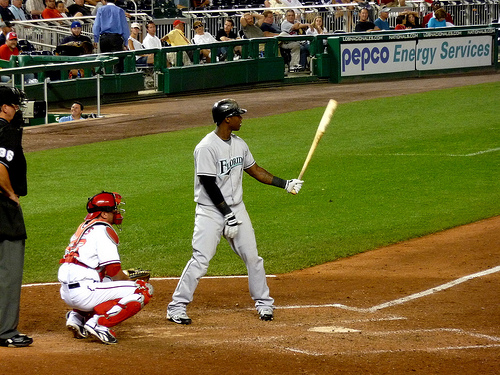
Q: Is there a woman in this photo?
A: No, there are no women.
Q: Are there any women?
A: No, there are no women.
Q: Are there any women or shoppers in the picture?
A: No, there are no women or shoppers.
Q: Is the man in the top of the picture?
A: Yes, the man is in the top of the image.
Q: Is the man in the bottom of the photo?
A: No, the man is in the top of the image.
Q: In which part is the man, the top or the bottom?
A: The man is in the top of the image.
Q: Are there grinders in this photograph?
A: No, there are no grinders.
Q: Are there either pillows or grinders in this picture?
A: No, there are no grinders or pillows.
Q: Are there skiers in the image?
A: No, there are no skiers.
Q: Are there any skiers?
A: No, there are no skiers.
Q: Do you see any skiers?
A: No, there are no skiers.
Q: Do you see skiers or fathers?
A: No, there are no skiers or fathers.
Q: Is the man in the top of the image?
A: Yes, the man is in the top of the image.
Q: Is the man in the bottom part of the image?
A: No, the man is in the top of the image.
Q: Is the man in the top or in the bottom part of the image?
A: The man is in the top of the image.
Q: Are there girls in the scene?
A: No, there are no girls.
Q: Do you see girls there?
A: No, there are no girls.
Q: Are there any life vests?
A: No, there are no life vests.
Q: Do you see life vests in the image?
A: No, there are no life vests.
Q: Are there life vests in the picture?
A: No, there are no life vests.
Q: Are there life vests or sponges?
A: No, there are no life vests or sponges.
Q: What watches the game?
A: The fan watches the game.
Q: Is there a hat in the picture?
A: Yes, there is a hat.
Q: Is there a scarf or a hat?
A: Yes, there is a hat.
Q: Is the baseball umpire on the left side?
A: Yes, the umpire is on the left of the image.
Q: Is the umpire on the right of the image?
A: No, the umpire is on the left of the image.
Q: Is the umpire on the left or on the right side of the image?
A: The umpire is on the left of the image.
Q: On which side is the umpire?
A: The umpire is on the left of the image.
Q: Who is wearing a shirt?
A: The umpire is wearing a shirt.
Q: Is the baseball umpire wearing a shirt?
A: Yes, the umpire is wearing a shirt.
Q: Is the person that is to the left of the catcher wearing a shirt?
A: Yes, the umpire is wearing a shirt.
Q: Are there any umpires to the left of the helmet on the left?
A: Yes, there is an umpire to the left of the helmet.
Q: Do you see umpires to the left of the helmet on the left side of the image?
A: Yes, there is an umpire to the left of the helmet.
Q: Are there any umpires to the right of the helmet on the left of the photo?
A: No, the umpire is to the left of the helmet.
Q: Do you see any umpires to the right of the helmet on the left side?
A: No, the umpire is to the left of the helmet.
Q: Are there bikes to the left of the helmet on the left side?
A: No, there is an umpire to the left of the helmet.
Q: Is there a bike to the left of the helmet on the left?
A: No, there is an umpire to the left of the helmet.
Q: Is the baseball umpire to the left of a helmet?
A: Yes, the umpire is to the left of a helmet.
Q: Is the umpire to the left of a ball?
A: No, the umpire is to the left of a helmet.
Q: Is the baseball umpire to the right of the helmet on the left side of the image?
A: No, the umpire is to the left of the helmet.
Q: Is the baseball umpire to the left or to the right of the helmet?
A: The umpire is to the left of the helmet.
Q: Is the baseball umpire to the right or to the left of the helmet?
A: The umpire is to the left of the helmet.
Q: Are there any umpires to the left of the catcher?
A: Yes, there is an umpire to the left of the catcher.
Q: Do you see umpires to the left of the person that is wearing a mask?
A: Yes, there is an umpire to the left of the catcher.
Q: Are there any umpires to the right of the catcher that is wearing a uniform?
A: No, the umpire is to the left of the catcher.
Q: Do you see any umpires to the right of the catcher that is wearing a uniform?
A: No, the umpire is to the left of the catcher.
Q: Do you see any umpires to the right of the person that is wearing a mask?
A: No, the umpire is to the left of the catcher.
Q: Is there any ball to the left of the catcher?
A: No, there is an umpire to the left of the catcher.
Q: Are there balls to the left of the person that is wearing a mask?
A: No, there is an umpire to the left of the catcher.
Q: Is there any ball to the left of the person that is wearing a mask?
A: No, there is an umpire to the left of the catcher.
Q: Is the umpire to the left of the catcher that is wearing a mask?
A: Yes, the umpire is to the left of the catcher.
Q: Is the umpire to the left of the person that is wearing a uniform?
A: Yes, the umpire is to the left of the catcher.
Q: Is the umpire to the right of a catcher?
A: No, the umpire is to the left of a catcher.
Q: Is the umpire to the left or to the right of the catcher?
A: The umpire is to the left of the catcher.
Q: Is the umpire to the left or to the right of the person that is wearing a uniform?
A: The umpire is to the left of the catcher.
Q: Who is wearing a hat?
A: The umpire is wearing a hat.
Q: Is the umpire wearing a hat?
A: Yes, the umpire is wearing a hat.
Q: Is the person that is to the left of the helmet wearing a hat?
A: Yes, the umpire is wearing a hat.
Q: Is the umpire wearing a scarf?
A: No, the umpire is wearing a hat.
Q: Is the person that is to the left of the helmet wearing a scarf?
A: No, the umpire is wearing a hat.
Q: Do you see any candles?
A: No, there are no candles.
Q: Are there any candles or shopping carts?
A: No, there are no candles or shopping carts.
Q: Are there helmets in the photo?
A: Yes, there is a helmet.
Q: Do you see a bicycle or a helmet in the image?
A: Yes, there is a helmet.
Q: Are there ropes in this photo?
A: No, there are no ropes.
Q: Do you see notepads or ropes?
A: No, there are no ropes or notepads.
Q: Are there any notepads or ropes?
A: No, there are no ropes or notepads.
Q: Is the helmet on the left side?
A: Yes, the helmet is on the left of the image.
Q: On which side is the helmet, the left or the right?
A: The helmet is on the left of the image.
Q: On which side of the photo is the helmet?
A: The helmet is on the left of the image.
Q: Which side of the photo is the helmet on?
A: The helmet is on the left of the image.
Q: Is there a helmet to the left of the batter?
A: Yes, there is a helmet to the left of the batter.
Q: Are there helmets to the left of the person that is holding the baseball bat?
A: Yes, there is a helmet to the left of the batter.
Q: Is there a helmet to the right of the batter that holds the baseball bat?
A: No, the helmet is to the left of the batter.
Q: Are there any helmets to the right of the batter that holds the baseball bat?
A: No, the helmet is to the left of the batter.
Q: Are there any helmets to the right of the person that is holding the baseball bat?
A: No, the helmet is to the left of the batter.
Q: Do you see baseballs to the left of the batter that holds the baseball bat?
A: No, there is a helmet to the left of the batter.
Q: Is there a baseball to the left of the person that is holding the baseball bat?
A: No, there is a helmet to the left of the batter.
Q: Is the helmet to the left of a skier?
A: No, the helmet is to the left of a batter.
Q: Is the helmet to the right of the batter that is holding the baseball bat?
A: No, the helmet is to the left of the batter.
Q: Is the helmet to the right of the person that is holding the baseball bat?
A: No, the helmet is to the left of the batter.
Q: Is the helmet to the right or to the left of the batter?
A: The helmet is to the left of the batter.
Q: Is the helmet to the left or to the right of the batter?
A: The helmet is to the left of the batter.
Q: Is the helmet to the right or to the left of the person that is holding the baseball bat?
A: The helmet is to the left of the batter.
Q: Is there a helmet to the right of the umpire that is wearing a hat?
A: Yes, there is a helmet to the right of the umpire.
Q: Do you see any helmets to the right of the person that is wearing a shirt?
A: Yes, there is a helmet to the right of the umpire.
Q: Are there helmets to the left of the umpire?
A: No, the helmet is to the right of the umpire.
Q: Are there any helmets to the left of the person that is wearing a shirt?
A: No, the helmet is to the right of the umpire.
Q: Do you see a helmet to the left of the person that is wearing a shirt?
A: No, the helmet is to the right of the umpire.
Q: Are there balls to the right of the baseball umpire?
A: No, there is a helmet to the right of the umpire.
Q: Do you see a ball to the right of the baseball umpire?
A: No, there is a helmet to the right of the umpire.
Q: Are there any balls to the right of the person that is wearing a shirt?
A: No, there is a helmet to the right of the umpire.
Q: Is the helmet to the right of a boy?
A: No, the helmet is to the right of the umpire.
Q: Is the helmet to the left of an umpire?
A: No, the helmet is to the right of an umpire.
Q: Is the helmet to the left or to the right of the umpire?
A: The helmet is to the right of the umpire.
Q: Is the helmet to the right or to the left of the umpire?
A: The helmet is to the right of the umpire.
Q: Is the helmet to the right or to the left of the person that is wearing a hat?
A: The helmet is to the right of the umpire.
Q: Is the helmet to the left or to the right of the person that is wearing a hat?
A: The helmet is to the right of the umpire.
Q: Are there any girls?
A: No, there are no girls.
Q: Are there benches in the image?
A: No, there are no benches.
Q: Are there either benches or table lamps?
A: No, there are no benches or table lamps.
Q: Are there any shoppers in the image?
A: No, there are no shoppers.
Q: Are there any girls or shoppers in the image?
A: No, there are no shoppers or girls.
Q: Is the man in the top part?
A: Yes, the man is in the top of the image.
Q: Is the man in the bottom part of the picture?
A: No, the man is in the top of the image.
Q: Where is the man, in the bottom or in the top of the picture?
A: The man is in the top of the image.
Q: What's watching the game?
A: The fan is watching the game.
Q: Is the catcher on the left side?
A: Yes, the catcher is on the left of the image.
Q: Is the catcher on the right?
A: No, the catcher is on the left of the image.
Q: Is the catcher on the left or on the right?
A: The catcher is on the left of the image.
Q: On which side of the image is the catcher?
A: The catcher is on the left of the image.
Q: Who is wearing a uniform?
A: The catcher is wearing a uniform.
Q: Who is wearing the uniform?
A: The catcher is wearing a uniform.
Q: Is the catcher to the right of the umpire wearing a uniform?
A: Yes, the catcher is wearing a uniform.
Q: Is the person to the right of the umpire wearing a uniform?
A: Yes, the catcher is wearing a uniform.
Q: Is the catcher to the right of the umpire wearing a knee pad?
A: No, the catcher is wearing a uniform.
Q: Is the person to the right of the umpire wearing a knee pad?
A: No, the catcher is wearing a uniform.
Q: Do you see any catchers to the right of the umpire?
A: Yes, there is a catcher to the right of the umpire.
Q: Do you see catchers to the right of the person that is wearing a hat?
A: Yes, there is a catcher to the right of the umpire.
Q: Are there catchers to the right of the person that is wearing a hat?
A: Yes, there is a catcher to the right of the umpire.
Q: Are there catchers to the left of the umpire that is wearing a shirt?
A: No, the catcher is to the right of the umpire.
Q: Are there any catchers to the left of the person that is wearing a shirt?
A: No, the catcher is to the right of the umpire.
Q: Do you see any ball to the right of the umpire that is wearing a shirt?
A: No, there is a catcher to the right of the umpire.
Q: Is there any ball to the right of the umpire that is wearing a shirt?
A: No, there is a catcher to the right of the umpire.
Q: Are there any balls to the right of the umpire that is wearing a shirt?
A: No, there is a catcher to the right of the umpire.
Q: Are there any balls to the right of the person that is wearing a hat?
A: No, there is a catcher to the right of the umpire.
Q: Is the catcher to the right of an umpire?
A: Yes, the catcher is to the right of an umpire.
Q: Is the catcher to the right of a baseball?
A: No, the catcher is to the right of an umpire.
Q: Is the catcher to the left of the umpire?
A: No, the catcher is to the right of the umpire.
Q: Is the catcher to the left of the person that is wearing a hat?
A: No, the catcher is to the right of the umpire.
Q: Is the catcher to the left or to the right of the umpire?
A: The catcher is to the right of the umpire.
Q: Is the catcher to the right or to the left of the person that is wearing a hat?
A: The catcher is to the right of the umpire.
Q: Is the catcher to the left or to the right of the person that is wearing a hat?
A: The catcher is to the right of the umpire.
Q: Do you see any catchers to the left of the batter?
A: Yes, there is a catcher to the left of the batter.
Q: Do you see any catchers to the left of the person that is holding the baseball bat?
A: Yes, there is a catcher to the left of the batter.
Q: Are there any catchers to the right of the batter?
A: No, the catcher is to the left of the batter.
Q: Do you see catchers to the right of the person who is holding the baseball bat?
A: No, the catcher is to the left of the batter.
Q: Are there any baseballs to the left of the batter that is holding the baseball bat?
A: No, there is a catcher to the left of the batter.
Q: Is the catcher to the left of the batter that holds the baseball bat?
A: Yes, the catcher is to the left of the batter.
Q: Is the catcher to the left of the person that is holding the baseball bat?
A: Yes, the catcher is to the left of the batter.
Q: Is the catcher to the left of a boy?
A: No, the catcher is to the left of the batter.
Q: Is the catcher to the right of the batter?
A: No, the catcher is to the left of the batter.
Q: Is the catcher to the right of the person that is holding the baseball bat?
A: No, the catcher is to the left of the batter.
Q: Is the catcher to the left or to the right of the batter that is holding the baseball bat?
A: The catcher is to the left of the batter.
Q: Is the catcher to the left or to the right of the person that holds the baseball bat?
A: The catcher is to the left of the batter.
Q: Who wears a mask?
A: The catcher wears a mask.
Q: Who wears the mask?
A: The catcher wears a mask.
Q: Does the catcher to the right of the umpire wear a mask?
A: Yes, the catcher wears a mask.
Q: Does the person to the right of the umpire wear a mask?
A: Yes, the catcher wears a mask.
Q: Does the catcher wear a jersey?
A: No, the catcher wears a mask.